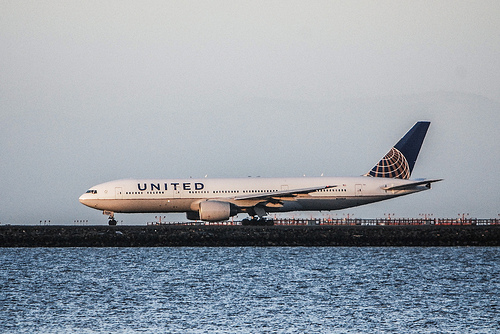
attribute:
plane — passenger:
[71, 106, 450, 254]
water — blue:
[0, 244, 498, 331]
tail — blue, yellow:
[363, 118, 430, 179]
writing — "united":
[136, 181, 203, 191]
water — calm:
[64, 259, 230, 301]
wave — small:
[218, 256, 310, 310]